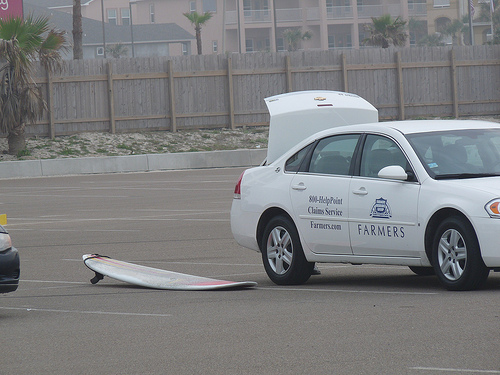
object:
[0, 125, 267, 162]
stones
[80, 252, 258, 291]
board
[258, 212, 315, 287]
wheel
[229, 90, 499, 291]
car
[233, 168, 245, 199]
blinker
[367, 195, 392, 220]
logo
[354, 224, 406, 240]
text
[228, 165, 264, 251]
tail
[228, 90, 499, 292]
trunk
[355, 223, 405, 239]
name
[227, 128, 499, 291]
side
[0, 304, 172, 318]
line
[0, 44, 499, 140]
fence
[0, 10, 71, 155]
tree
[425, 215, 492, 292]
tire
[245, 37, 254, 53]
window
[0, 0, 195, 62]
building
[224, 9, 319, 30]
balcony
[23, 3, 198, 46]
roof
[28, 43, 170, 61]
wall